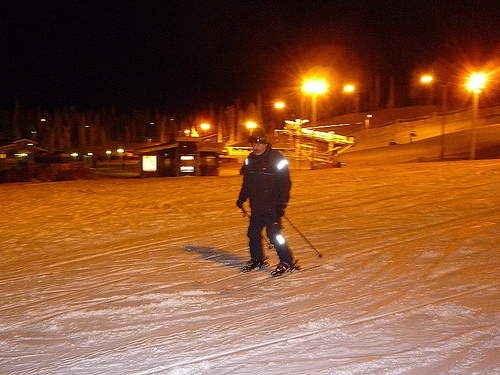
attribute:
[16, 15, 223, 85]
sky — dark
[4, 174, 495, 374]
field — snowy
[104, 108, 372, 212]
building —  small ,   wooden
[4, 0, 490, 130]
sky —  black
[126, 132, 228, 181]
building — small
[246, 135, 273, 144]
hat —  hat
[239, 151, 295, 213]
jacket —  black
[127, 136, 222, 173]
shed — small, wooden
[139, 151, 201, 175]
windows — illuminated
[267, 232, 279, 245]
knee —  man's 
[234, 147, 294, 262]
snow suit —  dark blue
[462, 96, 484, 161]
pole —  wooden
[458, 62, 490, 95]
light —  bright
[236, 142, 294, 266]
ski suit — dark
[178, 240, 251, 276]
shadow —  Person's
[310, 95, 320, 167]
pole — tall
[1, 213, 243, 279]
tracks —  clearly visible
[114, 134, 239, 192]
building —  small 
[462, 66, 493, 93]
light — bright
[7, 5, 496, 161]
sky — dark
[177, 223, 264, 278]
shadow —   Small,  black,  of man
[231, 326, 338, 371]
white snow —  Thick,  white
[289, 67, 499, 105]
lights — bright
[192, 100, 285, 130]
lights — bright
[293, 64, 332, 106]
lights — street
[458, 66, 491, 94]
light — orange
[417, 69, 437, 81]
light — orange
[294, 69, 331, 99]
light — orange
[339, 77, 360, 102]
light — orange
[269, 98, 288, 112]
light — orange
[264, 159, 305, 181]
light —  reflective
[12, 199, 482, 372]
snow — white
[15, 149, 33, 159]
window — illuminated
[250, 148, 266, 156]
beard —  short,  grey